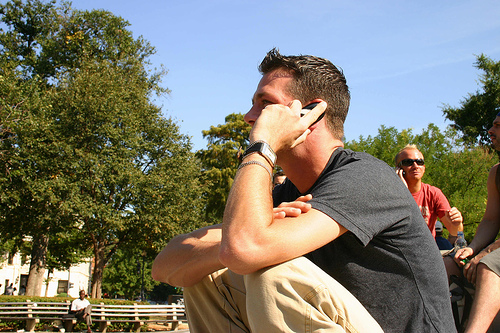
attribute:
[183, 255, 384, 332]
pants — khaki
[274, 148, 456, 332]
shirt — gray, black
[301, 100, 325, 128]
phone — black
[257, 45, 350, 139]
hair — gelled, brown, short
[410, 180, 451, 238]
shirt — red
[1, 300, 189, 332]
bench — wooden, white, gray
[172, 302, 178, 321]
post — white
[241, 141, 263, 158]
band — black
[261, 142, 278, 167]
face — rectangular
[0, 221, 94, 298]
building — white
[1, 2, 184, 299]
tree — green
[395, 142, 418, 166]
hair — blond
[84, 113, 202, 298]
tree — green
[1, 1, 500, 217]
sky — blue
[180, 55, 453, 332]
man — squatting, having conversation